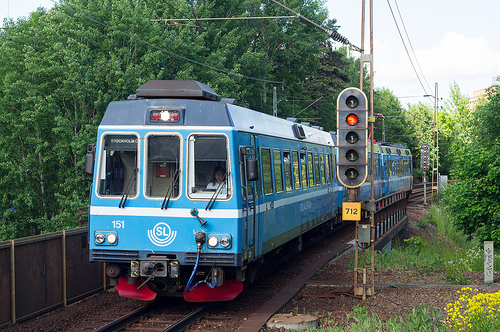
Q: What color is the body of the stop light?
A: Black.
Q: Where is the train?
A: On tracks.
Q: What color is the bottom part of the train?
A: Red.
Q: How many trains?
A: One.